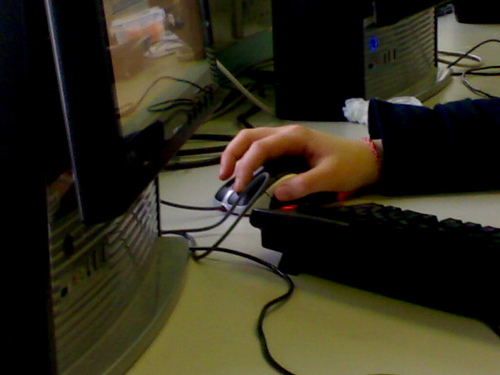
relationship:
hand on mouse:
[217, 126, 328, 183] [207, 169, 301, 224]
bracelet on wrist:
[364, 131, 386, 174] [343, 121, 386, 194]